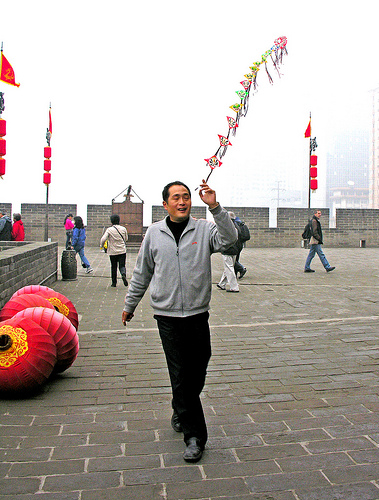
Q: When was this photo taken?
A: During the day.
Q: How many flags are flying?
A: 3.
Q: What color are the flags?
A: Red.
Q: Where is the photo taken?
A: In a city.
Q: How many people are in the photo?
A: 9.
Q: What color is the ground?
A: Brown.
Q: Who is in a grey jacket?
A: A man.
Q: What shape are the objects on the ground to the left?
A: Round.